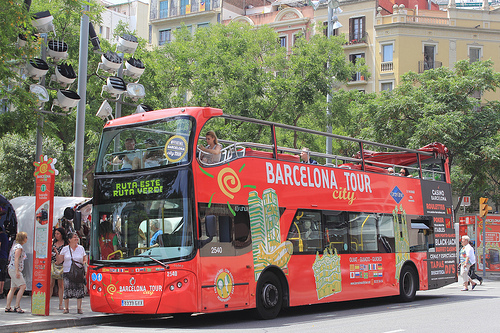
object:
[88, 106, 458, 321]
bus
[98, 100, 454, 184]
top deck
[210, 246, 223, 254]
2540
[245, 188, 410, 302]
buildings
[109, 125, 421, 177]
passengers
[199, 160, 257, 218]
picture of sun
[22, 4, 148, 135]
street light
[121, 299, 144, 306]
license plate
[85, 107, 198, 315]
front of bus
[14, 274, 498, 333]
street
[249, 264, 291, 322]
wheel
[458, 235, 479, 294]
woman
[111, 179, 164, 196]
green letters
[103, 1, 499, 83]
buildings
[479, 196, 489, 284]
traffic light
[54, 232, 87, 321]
women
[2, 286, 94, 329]
sidewalk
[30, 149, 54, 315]
sign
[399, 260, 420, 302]
rear wheel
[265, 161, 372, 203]
words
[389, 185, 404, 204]
logo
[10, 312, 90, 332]
curb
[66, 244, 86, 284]
bag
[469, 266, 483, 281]
tan pants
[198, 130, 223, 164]
woman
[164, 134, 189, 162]
top sign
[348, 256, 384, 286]
flag designs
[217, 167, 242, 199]
sun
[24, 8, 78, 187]
poles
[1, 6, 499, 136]
trees